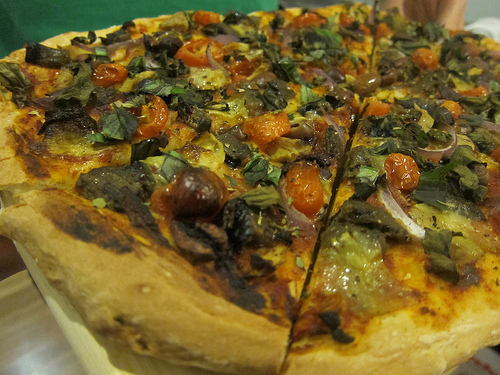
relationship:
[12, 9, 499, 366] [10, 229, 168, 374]
pizza on top of tray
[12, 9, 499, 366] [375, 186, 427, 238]
pizza has onions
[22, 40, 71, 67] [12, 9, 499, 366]
meat on pizza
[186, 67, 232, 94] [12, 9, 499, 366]
sauce on pizza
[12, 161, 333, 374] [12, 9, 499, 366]
crust on pizza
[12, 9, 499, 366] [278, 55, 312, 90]
pizza covered in peppers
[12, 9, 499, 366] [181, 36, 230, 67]
pizza has tomatoes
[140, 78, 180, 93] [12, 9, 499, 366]
kale on pizza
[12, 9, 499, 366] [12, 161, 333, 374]
pizza has crust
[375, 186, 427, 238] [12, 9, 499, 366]
onions on pizza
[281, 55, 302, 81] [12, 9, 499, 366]
peppers on pizza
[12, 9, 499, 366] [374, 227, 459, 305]
pizza has cheese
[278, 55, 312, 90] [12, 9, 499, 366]
peppers on pizza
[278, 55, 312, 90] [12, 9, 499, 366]
peppers on top of pizza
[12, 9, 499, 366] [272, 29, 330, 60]
pizza has toppings